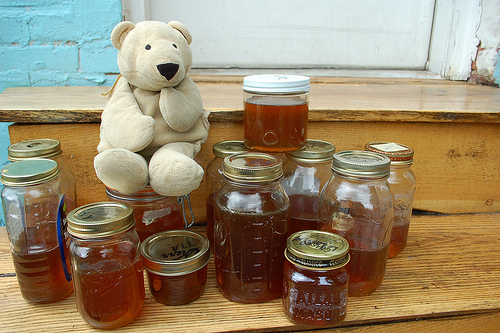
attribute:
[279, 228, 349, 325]
jar — filled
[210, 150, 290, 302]
jar — large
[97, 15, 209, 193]
bear — brown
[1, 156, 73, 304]
jar — rounded, honey comb shaped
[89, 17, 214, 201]
toy — black, white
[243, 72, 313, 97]
lid — white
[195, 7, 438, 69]
door — white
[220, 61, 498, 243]
wooden steps — brown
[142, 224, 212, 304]
jar — honey, small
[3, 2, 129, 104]
brick wall — blue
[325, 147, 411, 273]
jar — half full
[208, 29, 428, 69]
window pane — white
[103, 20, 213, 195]
teddy bear — white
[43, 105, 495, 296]
counter — brown, grainy, wooden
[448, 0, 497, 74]
door frame — white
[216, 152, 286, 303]
jar — honey, full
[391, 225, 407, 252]
liquid — brown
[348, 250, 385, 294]
liquid — brown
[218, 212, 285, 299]
liquid — brown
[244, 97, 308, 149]
liquid — brown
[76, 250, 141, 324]
liquid — brown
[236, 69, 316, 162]
jar — White 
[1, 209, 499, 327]
counter — wood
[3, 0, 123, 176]
paint — old, peeling, light blue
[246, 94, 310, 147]
honey — orange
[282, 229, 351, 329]
jar — sealed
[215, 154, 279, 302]
jar — sealed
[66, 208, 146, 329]
jar — sealed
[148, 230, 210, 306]
jar — sealed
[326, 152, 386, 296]
jar — sealed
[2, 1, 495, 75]
paint — old, cracked, peeling